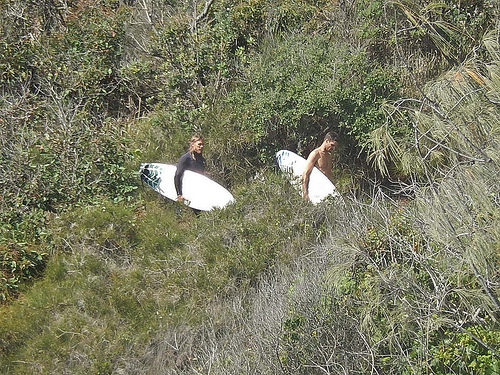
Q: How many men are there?
A: Two.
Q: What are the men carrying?
A: Surfboards.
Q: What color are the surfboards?
A: White.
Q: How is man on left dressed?
A: In wetsuit.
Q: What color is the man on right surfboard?
A: White.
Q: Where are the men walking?
A: Through brush.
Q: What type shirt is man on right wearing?
A: Not wearing shirt.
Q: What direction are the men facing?
A: Right.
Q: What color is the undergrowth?
A: Brown and green.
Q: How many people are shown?
A: 2.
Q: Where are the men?
A: In the trees.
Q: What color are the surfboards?
A: White.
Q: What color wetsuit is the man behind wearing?
A: Black.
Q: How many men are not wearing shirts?
A: 1.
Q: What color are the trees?
A: Green.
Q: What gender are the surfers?
A: Male.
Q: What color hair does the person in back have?
A: Blonde.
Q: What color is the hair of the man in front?
A: Brown.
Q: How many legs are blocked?
A: 4.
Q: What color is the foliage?
A: Green.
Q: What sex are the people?
A: Male.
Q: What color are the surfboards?
A: White.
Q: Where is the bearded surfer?
A: On the left.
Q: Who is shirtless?
A: The surfer on the right.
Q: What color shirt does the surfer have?
A: Black.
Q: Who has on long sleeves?
A: The surfer on the left.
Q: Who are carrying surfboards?
A: Men.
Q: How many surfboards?
A: 2.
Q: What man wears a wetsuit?
A: The man in the rear.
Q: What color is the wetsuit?
A: Black.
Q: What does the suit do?
A: Keeps the man warm.